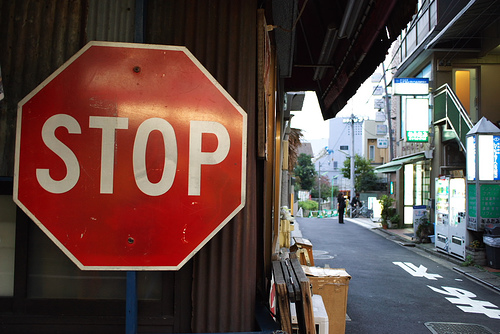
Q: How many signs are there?
A: 1.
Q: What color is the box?
A: Brown.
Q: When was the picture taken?
A: In the daytime.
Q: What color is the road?
A: Gray.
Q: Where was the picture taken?
A: On the side of a road.